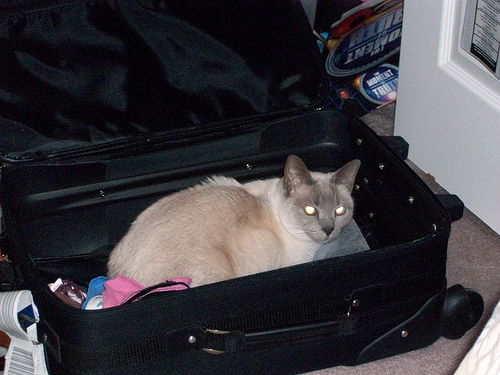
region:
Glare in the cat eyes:
[295, 201, 347, 218]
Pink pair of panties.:
[99, 274, 191, 310]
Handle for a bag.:
[189, 303, 374, 365]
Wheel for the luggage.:
[442, 275, 487, 347]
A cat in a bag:
[105, 145, 452, 362]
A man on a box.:
[336, 79, 369, 117]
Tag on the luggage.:
[0, 286, 48, 373]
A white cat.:
[107, 138, 360, 292]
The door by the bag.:
[393, 12, 498, 202]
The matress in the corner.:
[460, 317, 498, 373]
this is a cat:
[178, 182, 394, 288]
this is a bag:
[296, 286, 445, 368]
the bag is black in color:
[286, 285, 314, 299]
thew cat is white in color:
[191, 206, 230, 237]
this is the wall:
[403, 95, 469, 151]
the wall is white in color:
[428, 103, 478, 158]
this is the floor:
[453, 235, 497, 267]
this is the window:
[453, 15, 493, 33]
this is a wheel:
[458, 277, 485, 316]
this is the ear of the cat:
[279, 157, 304, 175]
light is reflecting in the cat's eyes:
[88, 151, 387, 293]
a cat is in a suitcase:
[54, 135, 442, 305]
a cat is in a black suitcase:
[43, 125, 476, 373]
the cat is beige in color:
[88, 147, 398, 299]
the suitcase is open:
[11, 21, 489, 373]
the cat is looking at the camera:
[97, 152, 392, 290]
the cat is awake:
[100, 147, 375, 304]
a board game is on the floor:
[317, 2, 402, 132]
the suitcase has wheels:
[431, 191, 493, 351]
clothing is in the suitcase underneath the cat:
[47, 143, 431, 328]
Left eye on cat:
[298, 198, 320, 227]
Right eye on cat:
[330, 196, 353, 231]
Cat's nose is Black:
[319, 224, 338, 238]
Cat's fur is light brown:
[148, 208, 243, 256]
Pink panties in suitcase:
[105, 279, 132, 304]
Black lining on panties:
[133, 282, 185, 292]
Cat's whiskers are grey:
[293, 222, 320, 242]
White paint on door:
[422, 78, 490, 168]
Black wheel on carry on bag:
[443, 275, 485, 343]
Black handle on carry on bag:
[191, 308, 368, 357]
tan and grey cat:
[104, 150, 361, 288]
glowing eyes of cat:
[300, 197, 347, 221]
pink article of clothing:
[99, 276, 199, 311]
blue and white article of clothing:
[82, 276, 118, 311]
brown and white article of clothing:
[42, 273, 86, 315]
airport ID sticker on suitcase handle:
[1, 286, 43, 373]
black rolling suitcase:
[6, 3, 487, 372]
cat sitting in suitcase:
[54, 101, 408, 318]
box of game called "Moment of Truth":
[330, 13, 414, 121]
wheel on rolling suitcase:
[445, 285, 489, 342]